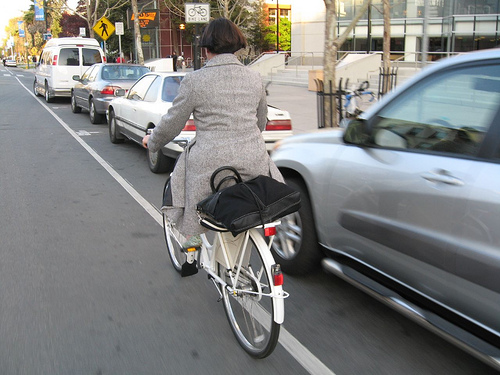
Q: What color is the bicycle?
A: White.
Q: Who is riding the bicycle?
A: The woman.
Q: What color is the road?
A: Gray.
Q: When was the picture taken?
A: Daytime.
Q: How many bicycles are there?
A: One.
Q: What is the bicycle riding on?
A: The road.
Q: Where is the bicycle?
A: On the road.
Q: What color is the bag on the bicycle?
A: Black.